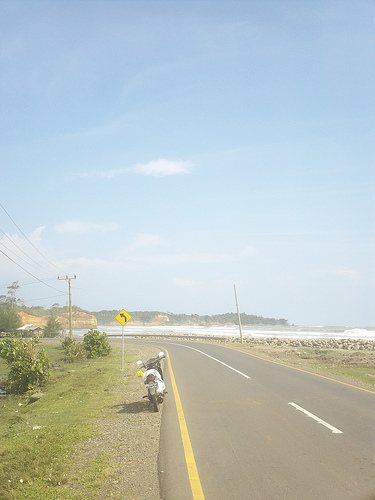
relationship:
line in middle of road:
[286, 400, 344, 434] [64, 334, 372, 498]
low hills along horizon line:
[1, 301, 295, 334] [1, 292, 373, 319]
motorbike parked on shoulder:
[136, 351, 168, 412] [116, 338, 189, 498]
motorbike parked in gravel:
[136, 351, 168, 412] [73, 340, 163, 499]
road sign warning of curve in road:
[101, 301, 131, 329] [144, 324, 370, 499]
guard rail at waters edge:
[102, 331, 229, 345] [62, 323, 373, 343]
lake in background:
[54, 306, 373, 358] [1, 19, 373, 350]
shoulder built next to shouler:
[66, 336, 166, 497] [79, 346, 162, 498]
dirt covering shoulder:
[102, 479, 161, 496] [66, 336, 166, 497]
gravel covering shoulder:
[77, 354, 163, 478] [66, 336, 166, 497]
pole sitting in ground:
[120, 323, 128, 376] [48, 333, 153, 498]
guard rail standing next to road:
[102, 331, 229, 345] [100, 338, 372, 498]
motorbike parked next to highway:
[136, 351, 168, 412] [0, 336, 373, 498]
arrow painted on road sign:
[108, 311, 148, 343] [115, 308, 131, 326]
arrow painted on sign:
[119, 312, 127, 322] [106, 304, 134, 373]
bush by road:
[80, 328, 109, 357] [154, 348, 313, 414]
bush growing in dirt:
[0, 334, 49, 397] [1, 331, 163, 498]